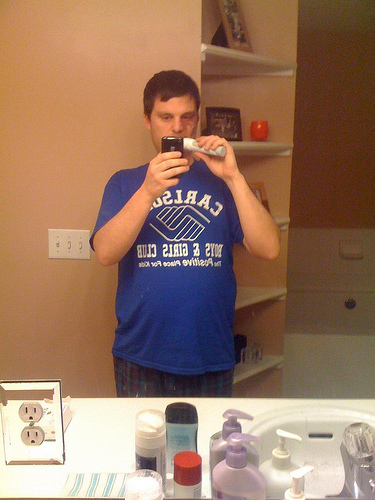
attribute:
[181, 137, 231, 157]
toothbrush — electric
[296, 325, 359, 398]
tub — white, part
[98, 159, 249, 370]
shirt — blue, white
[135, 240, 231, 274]
writing — white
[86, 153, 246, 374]
shirt — blue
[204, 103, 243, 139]
frane — photo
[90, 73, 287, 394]
bathtub — reflecting 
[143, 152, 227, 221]
hand — holding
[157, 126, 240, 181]
cellphone — black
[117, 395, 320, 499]
toiletries — full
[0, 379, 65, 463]
outlet — electrical, mirrored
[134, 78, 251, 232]
person — brushing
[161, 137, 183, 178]
cellphone — black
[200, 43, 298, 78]
shelf — white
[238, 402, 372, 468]
sink — white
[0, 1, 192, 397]
wall — white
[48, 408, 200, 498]
dish — white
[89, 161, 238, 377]
shirt — blue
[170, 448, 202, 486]
cap — red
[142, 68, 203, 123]
hair — short